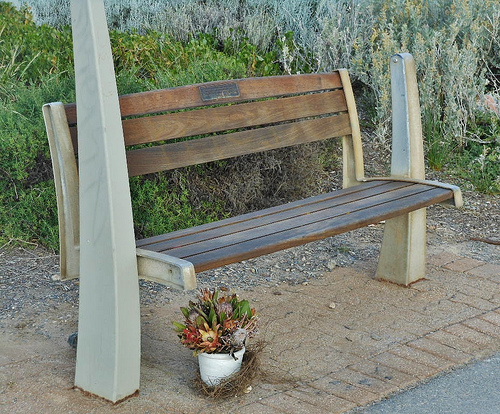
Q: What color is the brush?
A: Green.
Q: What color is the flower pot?
A: White.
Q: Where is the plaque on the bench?
A: On the back rest.